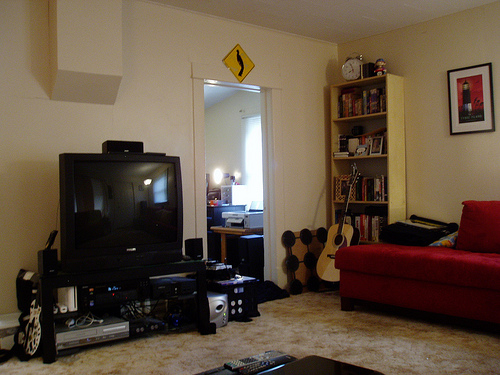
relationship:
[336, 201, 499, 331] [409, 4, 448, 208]
couch against wall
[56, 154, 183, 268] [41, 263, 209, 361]
television that black on stand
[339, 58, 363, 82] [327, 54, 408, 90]
clock on top of bookshelf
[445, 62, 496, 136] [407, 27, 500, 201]
picture on wall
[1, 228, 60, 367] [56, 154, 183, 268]
electric guitar near television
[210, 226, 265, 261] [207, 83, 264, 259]
table inside kitchen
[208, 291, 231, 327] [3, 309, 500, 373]
silver speaker on ground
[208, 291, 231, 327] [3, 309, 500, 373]
speaker silver colored on the ground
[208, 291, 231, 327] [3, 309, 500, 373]
silver stereo speaker on the ground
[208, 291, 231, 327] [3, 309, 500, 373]
stereo speaker silver colored on the ground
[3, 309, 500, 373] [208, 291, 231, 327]
ground has a silver speaker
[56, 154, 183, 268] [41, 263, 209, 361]
television set on a black stand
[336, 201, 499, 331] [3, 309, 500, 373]
red couch on carpet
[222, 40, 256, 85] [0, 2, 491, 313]
sign on white wall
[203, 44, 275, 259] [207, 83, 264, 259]
entrance to next room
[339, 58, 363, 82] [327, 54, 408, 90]
clock on top of the shelf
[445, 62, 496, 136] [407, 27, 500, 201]
painting on wall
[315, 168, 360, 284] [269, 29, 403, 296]
guitar in corner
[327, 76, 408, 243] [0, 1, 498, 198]
bookshelf near corner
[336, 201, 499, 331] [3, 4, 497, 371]
there is a red couch in room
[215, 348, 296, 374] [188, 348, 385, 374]
remote control on table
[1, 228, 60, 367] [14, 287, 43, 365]
here is a guitar that black and white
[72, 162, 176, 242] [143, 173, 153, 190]
screen has a light reflecting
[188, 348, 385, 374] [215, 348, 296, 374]
coffee table has many remotes on it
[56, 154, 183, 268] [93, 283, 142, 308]
tv has a black cable box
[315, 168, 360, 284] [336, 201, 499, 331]
acoustic guitar near sofa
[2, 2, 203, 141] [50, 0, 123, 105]
white wall has an inset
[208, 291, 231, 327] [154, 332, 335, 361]
stereo speaker on ground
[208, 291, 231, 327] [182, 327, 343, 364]
stereo speaker on ground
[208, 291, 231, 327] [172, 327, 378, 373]
speaker that is on ground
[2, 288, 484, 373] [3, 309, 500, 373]
carpet on floor